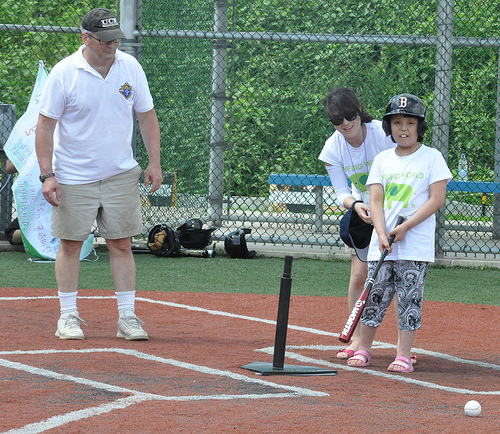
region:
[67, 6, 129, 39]
man has black cap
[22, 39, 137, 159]
man has white shirt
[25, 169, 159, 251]
man has tan shorts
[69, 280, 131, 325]
man has white socks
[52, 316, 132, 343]
man has grey shoes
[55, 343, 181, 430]
white lines on field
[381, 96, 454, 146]
girl has black helmet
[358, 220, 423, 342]
black and white pants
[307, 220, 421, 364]
black and red bat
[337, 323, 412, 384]
girl has pink shoes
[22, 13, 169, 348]
Man wearing a white shirt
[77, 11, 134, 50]
Hat on man's head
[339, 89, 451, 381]
Girl standing on a field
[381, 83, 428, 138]
Helmet on girl's head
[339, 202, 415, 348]
Baseball bat in girl's hand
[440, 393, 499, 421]
White ball on the ground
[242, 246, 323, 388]
Black stick on field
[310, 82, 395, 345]
Lady wearing a white shirt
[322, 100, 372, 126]
Sunglasses on the man's face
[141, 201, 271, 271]
Equipment in the background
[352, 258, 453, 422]
the girl has a bat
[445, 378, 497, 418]
a baseball is on the ground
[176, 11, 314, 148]
a metal gate is behind the field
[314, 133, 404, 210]
the woman is wearing a white shirt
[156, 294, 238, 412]
white lines are on the turf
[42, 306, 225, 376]
the man is wearing white shoes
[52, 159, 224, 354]
the man is wearing khaki shorts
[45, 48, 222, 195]
the man is wearing a white shirt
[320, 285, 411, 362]
the girl is wearing floral pants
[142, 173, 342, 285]
baseball hats are on the ground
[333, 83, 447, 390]
The girl is holding a baseball bat.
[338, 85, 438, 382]
The girl is wearing a baseball helmet.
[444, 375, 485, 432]
The baseball is lying on the ground.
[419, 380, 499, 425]
The baseball is white.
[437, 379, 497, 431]
The baseball is round.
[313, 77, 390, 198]
The woman is smiling.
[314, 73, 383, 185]
The woman is wearing sunglasses.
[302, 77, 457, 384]
The woman is standing behind the girl.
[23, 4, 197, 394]
The man is wearing a cap.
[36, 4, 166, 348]
The man is wearing glasses.